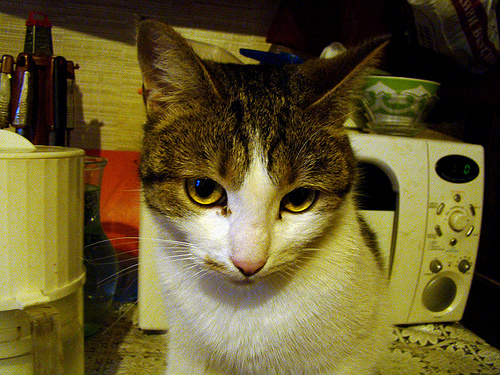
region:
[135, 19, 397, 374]
A cute white and tabby cat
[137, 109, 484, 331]
A dirty white microwave behind the cat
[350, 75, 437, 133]
A green bowl and plastic bowl stacked on top of the microwave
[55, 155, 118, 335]
A vase with blue liquid next to the microwave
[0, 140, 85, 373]
A dirty white plastic food processor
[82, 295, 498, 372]
A counter or table with non-slip lining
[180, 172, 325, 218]
The cat's amber, runny eyes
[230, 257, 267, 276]
The cat's small, pale pink nose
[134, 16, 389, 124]
The cat's ears tilted in curiosity or alertness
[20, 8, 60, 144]
A brown glass bottle in the back of the counter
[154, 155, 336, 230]
Yellow cat's eyes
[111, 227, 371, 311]
White cat whiskers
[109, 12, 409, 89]
Dark cat ears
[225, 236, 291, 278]
White cat nose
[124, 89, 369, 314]
White, gray and black cat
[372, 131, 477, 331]
Microwave buttons and dials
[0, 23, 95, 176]
Hanging kitchen utensils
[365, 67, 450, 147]
Green bowl on top of a microwave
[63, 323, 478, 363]
White flower plastic table cloth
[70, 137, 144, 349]
Vase filled with water on a kitchen table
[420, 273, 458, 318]
button on the microwave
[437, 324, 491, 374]
a fold int he tablecloth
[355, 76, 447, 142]
glass bowl on the microwave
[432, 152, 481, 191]
timer ont he microwave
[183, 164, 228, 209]
the eye of the cat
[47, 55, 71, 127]
handle of a knife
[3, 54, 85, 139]
a rack for kitchen utensils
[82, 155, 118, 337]
a vase on the countertop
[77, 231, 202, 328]
the cats whiskers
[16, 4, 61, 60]
a silver cheese grater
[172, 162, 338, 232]
yellow colour eyes of the cat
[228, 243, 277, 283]
a pink colour nose of the cat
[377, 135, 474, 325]
white colour microwave ovan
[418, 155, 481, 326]
control button of microwave ovan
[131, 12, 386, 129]
ear of the cat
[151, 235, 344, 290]
white colour mustache of the cat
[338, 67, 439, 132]
a green colour bowl kept in a microwave ovan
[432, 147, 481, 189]
timer display of microwave ovan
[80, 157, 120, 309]
a jar kept near to microwave ovan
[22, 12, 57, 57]
silver vegetable peeler with plastic handle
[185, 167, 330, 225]
bright yellow cats eye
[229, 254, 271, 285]
pale pink cat nose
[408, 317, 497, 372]
white lace table cloth with flowers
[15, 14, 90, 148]
dark red utensil holder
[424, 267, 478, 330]
large grey button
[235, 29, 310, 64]
bright blue kitchen utensil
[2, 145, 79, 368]
white water pitcher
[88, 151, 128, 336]
clear glass vase with water inside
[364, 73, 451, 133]
small green and white bowl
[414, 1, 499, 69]
plastic bread bag